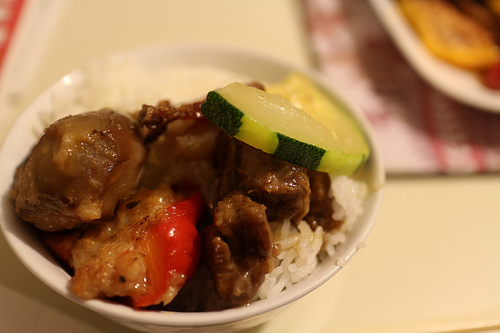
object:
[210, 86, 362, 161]
cucumber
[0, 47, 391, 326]
plate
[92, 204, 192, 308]
chicken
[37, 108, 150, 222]
beef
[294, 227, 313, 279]
rice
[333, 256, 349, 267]
rice grains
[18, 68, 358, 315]
meal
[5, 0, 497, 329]
table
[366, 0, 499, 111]
plate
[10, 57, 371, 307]
food